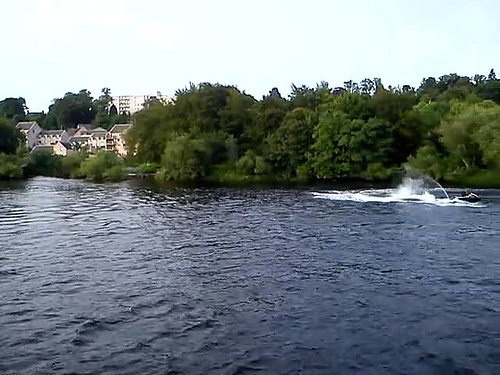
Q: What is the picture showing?
A: It is showing a lake.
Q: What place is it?
A: It is a lake.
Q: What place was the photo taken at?
A: It was taken at the lake.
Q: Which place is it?
A: It is a lake.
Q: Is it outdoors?
A: Yes, it is outdoors.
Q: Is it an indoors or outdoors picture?
A: It is outdoors.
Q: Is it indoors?
A: No, it is outdoors.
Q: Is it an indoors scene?
A: No, it is outdoors.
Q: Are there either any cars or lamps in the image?
A: No, there are no cars or lamps.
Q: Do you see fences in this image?
A: No, there are no fences.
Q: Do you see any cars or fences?
A: No, there are no fences or cars.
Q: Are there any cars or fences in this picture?
A: No, there are no fences or cars.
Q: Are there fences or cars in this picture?
A: No, there are no fences or cars.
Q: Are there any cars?
A: No, there are no cars.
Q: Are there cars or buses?
A: No, there are no cars or buses.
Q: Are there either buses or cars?
A: No, there are no cars or buses.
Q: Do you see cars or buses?
A: No, there are no cars or buses.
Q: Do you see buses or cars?
A: No, there are no cars or buses.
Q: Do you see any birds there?
A: No, there are no birds.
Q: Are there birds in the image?
A: No, there are no birds.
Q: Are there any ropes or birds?
A: No, there are no birds or ropes.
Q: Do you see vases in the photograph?
A: No, there are no vases.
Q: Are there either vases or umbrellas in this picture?
A: No, there are no vases or umbrellas.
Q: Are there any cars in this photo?
A: No, there are no cars.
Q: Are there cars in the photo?
A: No, there are no cars.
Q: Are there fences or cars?
A: No, there are no cars or fences.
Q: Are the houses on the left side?
A: Yes, the houses are on the left of the image.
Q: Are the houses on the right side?
A: No, the houses are on the left of the image.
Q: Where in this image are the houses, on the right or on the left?
A: The houses are on the left of the image.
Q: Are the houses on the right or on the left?
A: The houses are on the left of the image.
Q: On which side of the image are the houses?
A: The houses are on the left of the image.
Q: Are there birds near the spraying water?
A: No, there are houses near the water.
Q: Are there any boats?
A: Yes, there is a boat.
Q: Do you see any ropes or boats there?
A: Yes, there is a boat.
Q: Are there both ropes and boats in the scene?
A: No, there is a boat but no ropes.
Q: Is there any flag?
A: No, there are no flags.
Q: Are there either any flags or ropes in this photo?
A: No, there are no flags or ropes.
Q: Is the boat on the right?
A: Yes, the boat is on the right of the image.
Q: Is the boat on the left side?
A: No, the boat is on the right of the image.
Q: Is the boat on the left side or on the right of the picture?
A: The boat is on the right of the image.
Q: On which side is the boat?
A: The boat is on the right of the image.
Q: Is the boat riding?
A: Yes, the boat is riding.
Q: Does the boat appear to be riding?
A: Yes, the boat is riding.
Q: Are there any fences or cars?
A: No, there are no cars or fences.